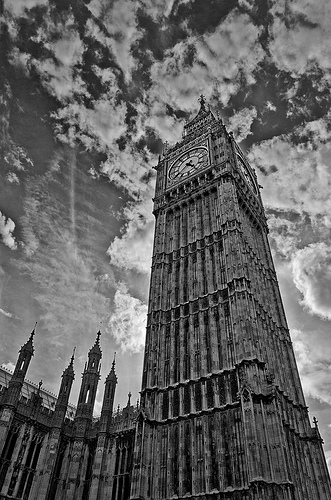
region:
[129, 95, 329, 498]
tall gothic tower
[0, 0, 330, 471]
sky behind the tower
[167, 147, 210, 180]
clock face on the side of the tower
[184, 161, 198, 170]
black hour hand on clock face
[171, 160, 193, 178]
black minute hand on clock face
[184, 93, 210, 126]
pointy spire on top of tower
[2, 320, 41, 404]
turret on building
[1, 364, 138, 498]
main building attached to tower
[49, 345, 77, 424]
turret to the right of turret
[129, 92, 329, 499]
tower in front of sky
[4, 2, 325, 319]
The sky is cloudy.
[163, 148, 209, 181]
The clock is on the top of the building.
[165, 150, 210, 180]
The hands are black.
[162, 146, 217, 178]
The numbers are black.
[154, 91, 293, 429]
The building is tall.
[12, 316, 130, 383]
The tops are steep.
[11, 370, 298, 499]
The building is large.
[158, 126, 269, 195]
two clock faces.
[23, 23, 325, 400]
The sun is behind the building.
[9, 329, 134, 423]
Windows are in the building.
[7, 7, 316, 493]
a black and white photograph of Big Ben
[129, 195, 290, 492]
The gothic inspired arches on a tower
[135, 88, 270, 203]
Clock at the top of a tower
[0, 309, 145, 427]
Gothic spires on a building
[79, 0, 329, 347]
bright clouds in the sky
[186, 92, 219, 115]
the spire on a clock tower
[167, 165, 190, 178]
a large minute hand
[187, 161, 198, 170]
a large hour hand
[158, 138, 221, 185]
a large clock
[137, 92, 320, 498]
a tall clock tower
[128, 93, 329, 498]
Clock tower attached to cathedral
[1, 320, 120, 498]
Fancy external towers of cathedral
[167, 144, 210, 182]
Round clock face on tower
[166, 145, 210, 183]
Clock face showing time of 5:40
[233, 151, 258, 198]
Clock face barely visible on side of tower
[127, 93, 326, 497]
Very tall and ornate structure bearing clock faces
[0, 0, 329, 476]
Sky full of fluffy white clouds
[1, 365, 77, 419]
Roof of central part of cathedral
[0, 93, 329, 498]
Very large and ornate cathedral-like building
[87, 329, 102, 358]
Cap and spire on top of corner tower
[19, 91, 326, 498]
a bit tower of a building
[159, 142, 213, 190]
a clock in front a tower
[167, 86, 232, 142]
steeple on top of tower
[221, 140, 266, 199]
a clock on side a tower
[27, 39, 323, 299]
a cloudy sky on the background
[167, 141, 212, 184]
clock has roman numerals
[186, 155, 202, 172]
hour handle of clock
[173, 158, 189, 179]
minute handle of clock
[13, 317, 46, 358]
a steeple on small tower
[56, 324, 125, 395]
steeples on small towers